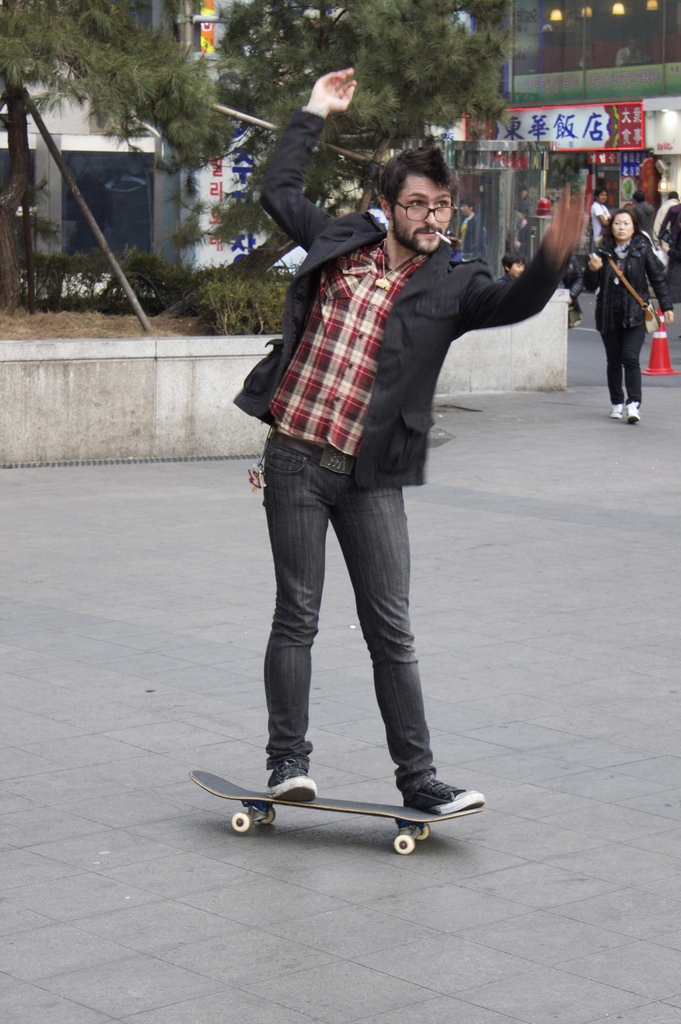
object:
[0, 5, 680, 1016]
picture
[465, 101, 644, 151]
letter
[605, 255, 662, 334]
brown purse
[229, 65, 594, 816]
man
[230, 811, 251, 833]
wheel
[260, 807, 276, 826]
wheel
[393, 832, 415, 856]
wheel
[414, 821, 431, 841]
wheel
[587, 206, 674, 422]
woman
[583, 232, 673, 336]
jacket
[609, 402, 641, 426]
shoes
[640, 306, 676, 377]
cone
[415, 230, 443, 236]
mouth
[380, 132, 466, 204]
hair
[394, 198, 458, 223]
glasses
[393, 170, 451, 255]
face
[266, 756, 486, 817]
shoes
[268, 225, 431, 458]
shirt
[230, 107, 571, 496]
jacket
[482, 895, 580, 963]
tile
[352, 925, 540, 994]
tile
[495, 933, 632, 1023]
tile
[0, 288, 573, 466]
box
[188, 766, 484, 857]
skateboard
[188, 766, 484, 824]
top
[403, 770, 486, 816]
skater shoe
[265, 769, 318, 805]
skater shoe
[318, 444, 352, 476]
buckle